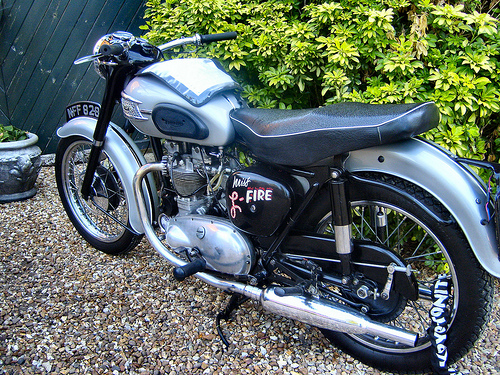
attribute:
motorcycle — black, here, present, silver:
[79, 31, 398, 306]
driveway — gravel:
[10, 174, 219, 374]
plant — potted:
[0, 130, 40, 156]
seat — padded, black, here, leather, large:
[282, 87, 452, 151]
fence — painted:
[38, 13, 126, 91]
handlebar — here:
[75, 28, 273, 74]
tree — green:
[213, 3, 496, 85]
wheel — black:
[50, 133, 162, 236]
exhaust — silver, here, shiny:
[254, 273, 403, 359]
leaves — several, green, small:
[241, 21, 331, 84]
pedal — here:
[168, 246, 222, 284]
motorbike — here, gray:
[160, 93, 452, 314]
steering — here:
[51, 23, 404, 143]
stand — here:
[203, 302, 250, 353]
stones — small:
[100, 288, 185, 338]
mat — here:
[158, 42, 239, 112]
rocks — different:
[19, 286, 106, 359]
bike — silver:
[144, 107, 299, 275]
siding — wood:
[7, 26, 56, 103]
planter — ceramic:
[11, 128, 60, 233]